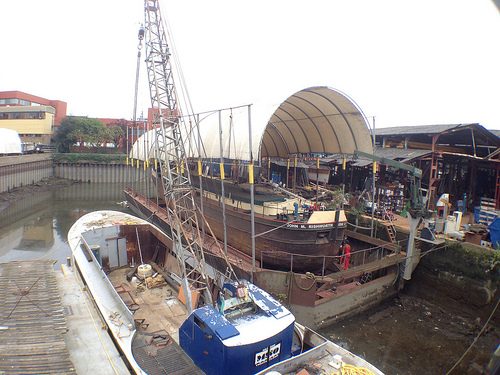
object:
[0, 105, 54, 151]
building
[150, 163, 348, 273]
boat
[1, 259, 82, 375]
pier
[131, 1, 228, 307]
crane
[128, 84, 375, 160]
canopy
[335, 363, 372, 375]
rope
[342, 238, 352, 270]
person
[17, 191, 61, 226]
water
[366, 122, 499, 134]
roof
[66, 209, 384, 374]
boat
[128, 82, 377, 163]
tent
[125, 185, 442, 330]
dock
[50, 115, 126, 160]
group of trees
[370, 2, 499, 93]
sky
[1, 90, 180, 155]
building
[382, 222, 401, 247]
ladder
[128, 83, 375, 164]
roof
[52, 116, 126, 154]
trees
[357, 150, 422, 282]
lift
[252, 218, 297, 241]
rope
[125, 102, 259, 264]
bracing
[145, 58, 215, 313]
rods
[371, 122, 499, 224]
shelter